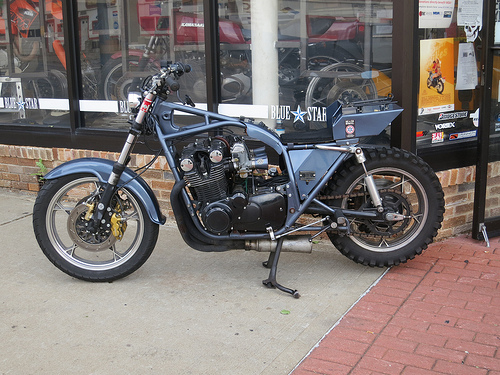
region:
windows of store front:
[2, 5, 397, 135]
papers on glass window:
[414, 3, 480, 145]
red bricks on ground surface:
[299, 235, 494, 373]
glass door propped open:
[472, 48, 498, 249]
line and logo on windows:
[0, 99, 325, 122]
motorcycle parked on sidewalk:
[30, 62, 444, 298]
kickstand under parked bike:
[259, 244, 298, 298]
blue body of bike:
[151, 100, 397, 242]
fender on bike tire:
[32, 157, 163, 283]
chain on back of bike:
[309, 190, 411, 238]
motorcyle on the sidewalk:
[23, 48, 464, 309]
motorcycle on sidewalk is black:
[6, 33, 461, 315]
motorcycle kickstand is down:
[253, 228, 308, 306]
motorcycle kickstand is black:
[260, 229, 307, 311]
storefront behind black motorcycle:
[2, 0, 499, 251]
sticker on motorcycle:
[336, 116, 358, 142]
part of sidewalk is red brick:
[267, 214, 499, 374]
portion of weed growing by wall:
[24, 156, 55, 193]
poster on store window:
[403, 29, 459, 124]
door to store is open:
[472, 1, 499, 248]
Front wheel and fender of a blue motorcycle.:
[31, 156, 165, 283]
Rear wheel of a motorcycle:
[325, 144, 445, 266]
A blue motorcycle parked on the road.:
[31, 60, 444, 299]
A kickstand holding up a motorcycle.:
[261, 230, 300, 298]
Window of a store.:
[4, 0, 395, 129]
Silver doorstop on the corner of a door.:
[476, 219, 491, 247]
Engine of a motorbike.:
[178, 133, 293, 234]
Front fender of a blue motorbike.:
[43, 158, 168, 225]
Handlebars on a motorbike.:
[147, 58, 192, 96]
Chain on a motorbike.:
[289, 188, 414, 236]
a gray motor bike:
[30, 38, 458, 318]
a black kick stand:
[243, 225, 310, 302]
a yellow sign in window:
[424, 38, 465, 130]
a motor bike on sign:
[416, 44, 458, 118]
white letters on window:
[262, 99, 351, 141]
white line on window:
[3, 77, 285, 144]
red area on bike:
[127, 94, 163, 121]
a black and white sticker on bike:
[341, 112, 367, 139]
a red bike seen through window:
[118, 5, 391, 121]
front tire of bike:
[13, 137, 168, 297]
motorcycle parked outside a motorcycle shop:
[28, 29, 451, 301]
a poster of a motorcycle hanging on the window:
[416, 30, 460, 120]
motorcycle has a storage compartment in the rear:
[321, 90, 409, 141]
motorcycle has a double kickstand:
[255, 237, 307, 304]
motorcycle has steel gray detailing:
[33, 88, 413, 237]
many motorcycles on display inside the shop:
[1, 0, 401, 136]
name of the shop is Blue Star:
[263, 95, 335, 126]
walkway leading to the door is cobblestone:
[292, 214, 499, 373]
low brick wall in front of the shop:
[1, 140, 208, 217]